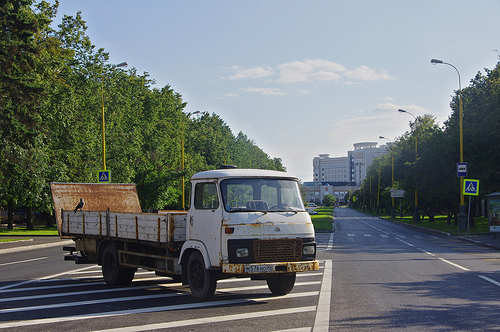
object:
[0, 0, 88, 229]
tall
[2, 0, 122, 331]
left